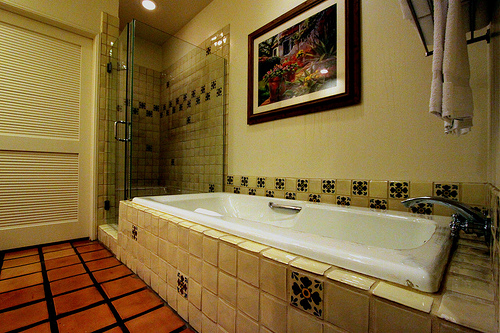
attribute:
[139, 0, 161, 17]
light — on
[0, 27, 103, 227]
wooden door — white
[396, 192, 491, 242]
faucet — chrome, bathtub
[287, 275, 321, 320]
tile — decorative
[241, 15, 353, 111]
painting — framed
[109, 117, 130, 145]
door handle — chrome, shower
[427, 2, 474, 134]
towel — hanging, tan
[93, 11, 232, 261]
shower — glass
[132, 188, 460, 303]
bath tub — white, porcelain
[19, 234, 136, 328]
floor — tiled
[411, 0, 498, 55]
rack — towel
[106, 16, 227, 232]
glass — clear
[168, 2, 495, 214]
wall — cream colored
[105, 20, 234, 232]
door — glass, shower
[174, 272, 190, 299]
tile — decorative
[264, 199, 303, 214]
bar — chrome, grab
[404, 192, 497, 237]
tap — metallic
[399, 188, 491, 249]
spout — silver, tub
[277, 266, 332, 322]
tile — decorative